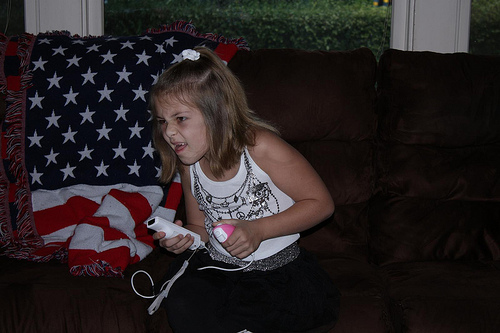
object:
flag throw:
[26, 21, 215, 297]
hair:
[141, 47, 248, 149]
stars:
[23, 51, 122, 180]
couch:
[6, 34, 499, 332]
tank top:
[173, 163, 293, 266]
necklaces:
[188, 149, 280, 219]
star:
[46, 108, 62, 128]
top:
[189, 159, 292, 258]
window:
[1, 0, 499, 50]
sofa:
[3, 31, 498, 331]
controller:
[211, 220, 234, 242]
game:
[144, 215, 233, 253]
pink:
[204, 220, 239, 248]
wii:
[202, 216, 235, 253]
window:
[135, 50, 392, 60]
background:
[0, 31, 499, 332]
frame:
[403, 50, 464, 56]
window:
[394, 100, 441, 103]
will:
[205, 220, 238, 248]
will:
[141, 212, 197, 256]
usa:
[38, 58, 138, 167]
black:
[164, 258, 429, 322]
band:
[179, 50, 200, 64]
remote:
[141, 213, 204, 253]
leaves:
[104, 0, 392, 60]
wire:
[122, 253, 249, 331]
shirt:
[180, 130, 308, 264]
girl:
[148, 50, 333, 328]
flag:
[10, 28, 242, 268]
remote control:
[136, 209, 239, 252]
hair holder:
[140, 53, 343, 331]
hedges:
[105, 0, 500, 47]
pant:
[167, 257, 312, 330]